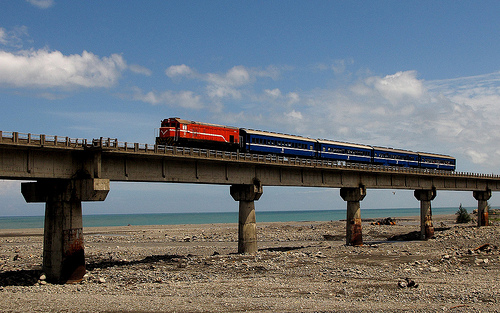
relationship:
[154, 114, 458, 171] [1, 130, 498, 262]
train on bridge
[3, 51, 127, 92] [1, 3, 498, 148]
clouds in sky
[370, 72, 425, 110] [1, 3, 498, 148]
clouds in sky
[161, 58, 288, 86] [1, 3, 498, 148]
clouds in sky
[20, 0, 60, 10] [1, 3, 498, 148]
clouds in sky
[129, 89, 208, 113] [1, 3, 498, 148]
clouds in sky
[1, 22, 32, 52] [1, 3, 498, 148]
clouds in sky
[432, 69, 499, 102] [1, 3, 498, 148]
clouds in sky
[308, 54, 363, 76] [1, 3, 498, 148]
clouds in sky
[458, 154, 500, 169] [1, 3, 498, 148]
clouds in sky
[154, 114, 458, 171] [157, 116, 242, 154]
train has car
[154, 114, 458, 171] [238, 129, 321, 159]
train has car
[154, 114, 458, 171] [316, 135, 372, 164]
train has car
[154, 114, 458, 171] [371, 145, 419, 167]
train has car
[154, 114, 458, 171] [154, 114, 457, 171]
train has train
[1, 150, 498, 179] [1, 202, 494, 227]
train tracks near ocean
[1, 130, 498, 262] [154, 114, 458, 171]
bridge supports train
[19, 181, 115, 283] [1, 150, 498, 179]
concrete supports train tracks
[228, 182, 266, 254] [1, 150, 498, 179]
concrete supports train tracks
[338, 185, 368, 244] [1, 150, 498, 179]
concrete supports train tracks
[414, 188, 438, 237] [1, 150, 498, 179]
concrete supports train tracks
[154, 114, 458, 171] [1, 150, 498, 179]
train on train tracks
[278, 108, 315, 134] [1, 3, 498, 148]
clouds in sky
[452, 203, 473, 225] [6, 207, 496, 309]
shrub in rocky area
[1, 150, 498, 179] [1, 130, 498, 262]
train tracks on bridge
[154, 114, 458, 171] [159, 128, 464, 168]
train has stripe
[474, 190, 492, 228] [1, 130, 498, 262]
concrete supports bridge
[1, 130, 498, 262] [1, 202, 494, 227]
bridge over ocean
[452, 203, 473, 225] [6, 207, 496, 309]
shrub on rocky area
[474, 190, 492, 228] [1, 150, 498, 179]
concrete supports train tracks